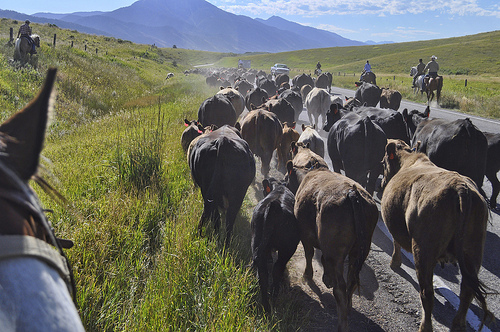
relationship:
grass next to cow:
[86, 133, 186, 223] [190, 121, 255, 211]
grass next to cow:
[86, 133, 186, 223] [243, 161, 304, 263]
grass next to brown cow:
[86, 133, 186, 223] [292, 151, 379, 320]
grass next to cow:
[86, 133, 186, 223] [365, 120, 499, 306]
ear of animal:
[2, 65, 55, 182] [0, 65, 85, 330]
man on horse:
[359, 60, 372, 81] [359, 70, 383, 89]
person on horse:
[407, 51, 424, 70] [407, 64, 424, 89]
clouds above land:
[233, 0, 492, 33] [280, 18, 494, 116]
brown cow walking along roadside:
[376, 133, 489, 332] [178, 52, 498, 326]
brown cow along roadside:
[292, 151, 379, 320] [201, 61, 493, 326]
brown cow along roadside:
[276, 117, 299, 169] [242, 82, 498, 329]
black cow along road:
[323, 103, 387, 198] [373, 247, 390, 318]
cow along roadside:
[404, 107, 479, 192] [201, 61, 493, 326]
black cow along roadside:
[245, 176, 299, 299] [201, 61, 493, 326]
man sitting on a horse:
[364, 50, 371, 63] [354, 65, 380, 83]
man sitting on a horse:
[426, 56, 443, 81] [423, 74, 443, 98]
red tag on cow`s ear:
[264, 182, 273, 194] [258, 177, 271, 195]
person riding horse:
[8, 16, 43, 65] [16, 20, 43, 62]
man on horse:
[359, 60, 372, 81] [189, 75, 345, 328]